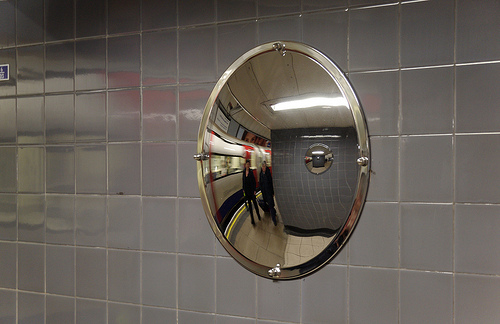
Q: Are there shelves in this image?
A: No, there are no shelves.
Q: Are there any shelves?
A: No, there are no shelves.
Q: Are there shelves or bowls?
A: No, there are no shelves or bowls.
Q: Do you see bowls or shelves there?
A: No, there are no shelves or bowls.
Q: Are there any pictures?
A: No, there are no pictures.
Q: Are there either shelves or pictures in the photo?
A: No, there are no pictures or shelves.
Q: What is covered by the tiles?
A: The wall is covered by the tiles.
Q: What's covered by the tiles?
A: The wall is covered by the tiles.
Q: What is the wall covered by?
A: The wall is covered by the tiles.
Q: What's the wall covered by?
A: The wall is covered by the tiles.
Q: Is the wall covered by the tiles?
A: Yes, the wall is covered by the tiles.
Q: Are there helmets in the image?
A: No, there are no helmets.